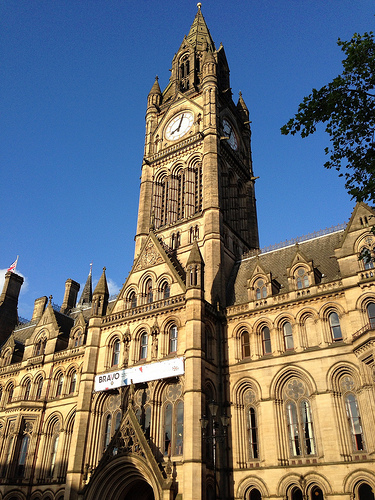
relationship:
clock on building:
[163, 109, 196, 143] [6, 31, 373, 499]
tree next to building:
[301, 71, 372, 158] [6, 31, 373, 499]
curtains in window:
[263, 363, 334, 458] [261, 359, 332, 472]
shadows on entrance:
[39, 459, 108, 490] [80, 409, 188, 494]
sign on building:
[85, 356, 197, 393] [6, 31, 373, 499]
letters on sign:
[88, 365, 133, 390] [72, 350, 200, 400]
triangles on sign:
[137, 365, 144, 371] [91, 354, 186, 392]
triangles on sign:
[120, 376, 129, 385] [91, 354, 186, 392]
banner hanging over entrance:
[89, 354, 187, 391] [80, 409, 179, 500]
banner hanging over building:
[94, 356, 185, 393] [71, 32, 229, 498]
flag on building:
[5, 246, 41, 279] [13, 89, 374, 468]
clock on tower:
[164, 109, 195, 142] [134, 2, 260, 258]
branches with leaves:
[288, 78, 357, 163] [288, 59, 373, 151]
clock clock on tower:
[164, 109, 195, 142] [132, 54, 268, 245]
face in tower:
[157, 104, 250, 156] [106, 78, 262, 270]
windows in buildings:
[3, 337, 370, 468] [7, 275, 360, 497]